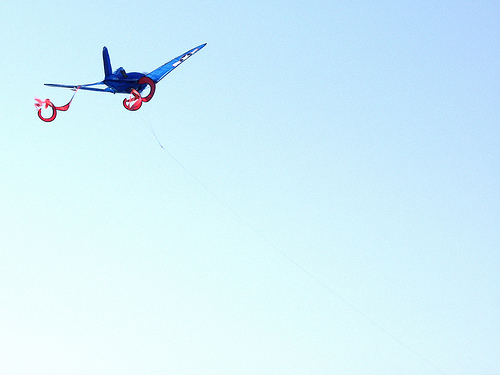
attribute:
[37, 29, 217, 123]
plane — blue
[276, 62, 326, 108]
sky — clear, blue, cloudy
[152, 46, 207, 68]
wing — blue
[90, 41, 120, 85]
tail — blue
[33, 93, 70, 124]
flag — red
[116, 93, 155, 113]
flag — red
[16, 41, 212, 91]
kite — blue